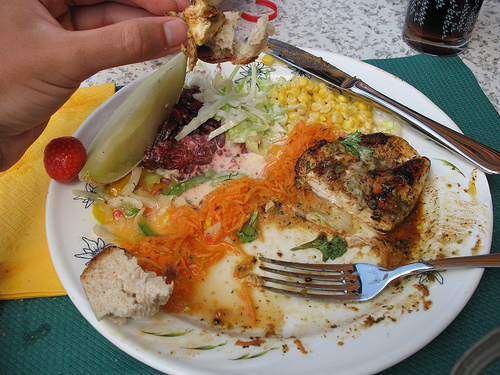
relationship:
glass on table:
[384, 12, 481, 71] [323, 15, 385, 63]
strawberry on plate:
[56, 145, 88, 183] [46, 209, 92, 264]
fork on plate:
[258, 220, 478, 331] [46, 209, 92, 264]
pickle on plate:
[87, 87, 175, 205] [46, 209, 92, 264]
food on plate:
[82, 59, 436, 373] [46, 209, 92, 264]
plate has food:
[46, 209, 92, 264] [82, 59, 436, 373]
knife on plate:
[262, 33, 466, 119] [46, 209, 92, 264]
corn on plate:
[288, 78, 375, 132] [46, 209, 92, 264]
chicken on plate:
[312, 166, 432, 230] [46, 209, 92, 264]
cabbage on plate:
[198, 83, 256, 194] [46, 209, 92, 264]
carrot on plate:
[82, 59, 436, 373] [46, 209, 92, 264]